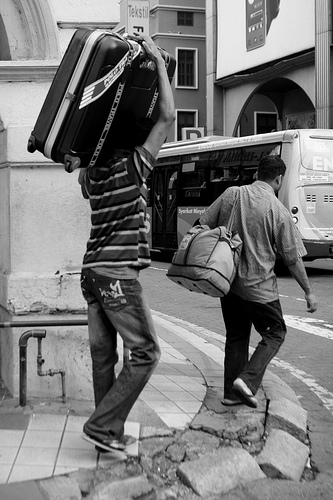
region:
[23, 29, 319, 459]
Two men walking on sidewalk carrying luggage.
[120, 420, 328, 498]
Crumbling curve of brick sidewalk.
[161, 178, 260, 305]
Carry all hanging from man's shoulder.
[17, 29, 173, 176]
Black suitcase on top of man's shoulder.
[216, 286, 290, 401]
Man dressed in blue jeans.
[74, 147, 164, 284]
Man dressed in striped t-shirt.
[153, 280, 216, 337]
A brick paved road.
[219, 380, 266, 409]
Man wearing flip flops on feet.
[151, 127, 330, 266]
Bus parked on side of street.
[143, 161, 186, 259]
Doors on side of bus.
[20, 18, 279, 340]
Person carrying a suitcase.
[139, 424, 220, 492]
Crumbled rocks on the ground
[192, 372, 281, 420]
Man wearing flip flops.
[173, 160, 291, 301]
Luggage on the man's back.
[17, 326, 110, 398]
Pipe on the street.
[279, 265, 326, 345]
White line on the road.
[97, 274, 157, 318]
Design on the man's jeans.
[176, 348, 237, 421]
Crack on the sidewalk.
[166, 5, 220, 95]
Windows on a building.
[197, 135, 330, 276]
Bus on the road.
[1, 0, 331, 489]
picture is in black and white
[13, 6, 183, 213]
the man is holding bag over his head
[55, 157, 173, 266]
the man's shirt is striped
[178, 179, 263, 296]
the man is carrying a bag over his shoulder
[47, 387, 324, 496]
the sidewalk is broken into pieces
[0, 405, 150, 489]
the sidewalk has squares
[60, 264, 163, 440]
the man is wearing jeans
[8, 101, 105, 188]
the luggage has wheels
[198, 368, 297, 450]
the man is wearing sandals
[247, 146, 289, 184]
the man's hair is black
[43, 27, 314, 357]
two travelers carrying luggage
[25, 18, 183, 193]
man holding suitcase on shoulder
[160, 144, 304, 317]
man carrying stuffed tote bag over shoulder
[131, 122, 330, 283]
bus on side street in front of men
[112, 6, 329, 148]
buildings and signs in back of bus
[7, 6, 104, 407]
thick corner building with pipe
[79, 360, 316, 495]
crumbling curb under men's feet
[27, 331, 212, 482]
square tiles covering sidewalk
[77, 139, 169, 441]
man wearing two shirts with jeans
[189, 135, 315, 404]
man wearing loose shirt over dark pants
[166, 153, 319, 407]
man carrying tan bag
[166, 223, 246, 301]
light colored bag being carried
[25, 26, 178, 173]
large dark suitcase on shoulder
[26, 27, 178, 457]
man carrying large suitcase on shoulder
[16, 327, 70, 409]
pipes jutting from concrete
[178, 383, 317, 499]
crumbled curb on side of road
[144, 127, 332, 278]
bus on city street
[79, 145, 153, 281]
tri-colored striped shirt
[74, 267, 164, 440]
jeans with writing on back pocket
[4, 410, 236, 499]
tiled sidewalk with crumbled curb